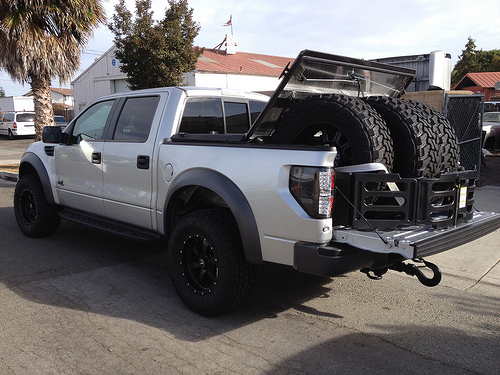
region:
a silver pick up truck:
[13, 48, 498, 320]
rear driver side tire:
[165, 213, 245, 317]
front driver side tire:
[15, 173, 52, 238]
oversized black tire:
[274, 91, 399, 213]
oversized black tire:
[365, 91, 460, 202]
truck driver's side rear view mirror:
[42, 123, 61, 144]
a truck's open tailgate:
[332, 205, 497, 262]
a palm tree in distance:
[0, 0, 105, 142]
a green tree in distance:
[104, 0, 204, 88]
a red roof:
[451, 71, 498, 89]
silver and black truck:
[35, 77, 375, 285]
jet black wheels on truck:
[155, 200, 239, 317]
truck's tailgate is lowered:
[313, 202, 485, 252]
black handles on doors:
[124, 150, 166, 182]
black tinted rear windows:
[184, 96, 270, 156]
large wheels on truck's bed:
[302, 80, 467, 210]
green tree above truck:
[95, 11, 197, 105]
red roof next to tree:
[172, 27, 339, 97]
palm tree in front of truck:
[11, 1, 78, 148]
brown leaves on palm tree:
[12, 3, 95, 79]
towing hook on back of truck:
[399, 258, 446, 286]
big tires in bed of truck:
[267, 91, 459, 211]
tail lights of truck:
[285, 163, 335, 218]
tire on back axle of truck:
[162, 208, 252, 320]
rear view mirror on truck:
[40, 123, 67, 146]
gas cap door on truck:
[157, 160, 176, 182]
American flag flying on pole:
[223, 15, 234, 27]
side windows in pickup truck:
[65, 93, 171, 148]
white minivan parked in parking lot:
[0, 108, 39, 140]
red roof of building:
[452, 69, 498, 91]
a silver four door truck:
[13, 43, 498, 317]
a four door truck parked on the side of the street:
[0, 45, 499, 373]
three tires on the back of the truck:
[275, 93, 461, 228]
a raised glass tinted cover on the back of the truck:
[248, 50, 418, 140]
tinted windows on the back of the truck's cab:
[177, 97, 266, 134]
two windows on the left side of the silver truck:
[67, 97, 159, 144]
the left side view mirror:
[42, 124, 66, 145]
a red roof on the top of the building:
[197, 48, 295, 76]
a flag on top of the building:
[220, 11, 237, 38]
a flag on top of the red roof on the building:
[195, 13, 290, 70]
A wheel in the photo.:
[162, 200, 240, 314]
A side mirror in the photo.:
[37, 124, 67, 146]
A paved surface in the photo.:
[85, 318, 165, 366]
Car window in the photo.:
[108, 94, 154, 146]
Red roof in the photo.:
[213, 46, 269, 73]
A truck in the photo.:
[20, 85, 490, 310]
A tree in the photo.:
[1, 1, 75, 127]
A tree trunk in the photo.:
[30, 76, 60, 126]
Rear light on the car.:
[285, 165, 337, 222]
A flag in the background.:
[223, 14, 243, 39]